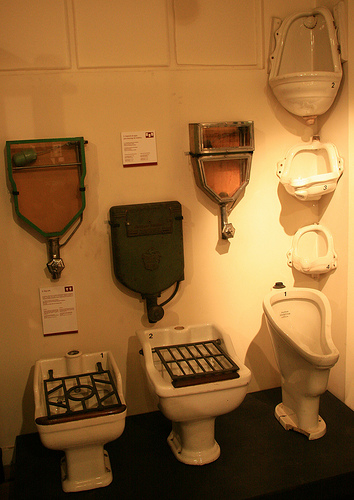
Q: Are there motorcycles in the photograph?
A: No, there are no motorcycles.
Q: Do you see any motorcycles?
A: No, there are no motorcycles.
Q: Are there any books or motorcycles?
A: No, there are no motorcycles or books.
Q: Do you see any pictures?
A: No, there are no pictures.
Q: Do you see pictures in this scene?
A: No, there are no pictures.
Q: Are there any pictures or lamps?
A: No, there are no pictures or lamps.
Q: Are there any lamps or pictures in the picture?
A: No, there are no pictures or lamps.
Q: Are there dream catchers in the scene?
A: No, there are no dream catchers.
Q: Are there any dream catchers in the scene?
A: No, there are no dream catchers.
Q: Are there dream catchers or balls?
A: No, there are no dream catchers or balls.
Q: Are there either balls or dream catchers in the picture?
A: No, there are no dream catchers or balls.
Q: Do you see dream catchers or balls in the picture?
A: No, there are no dream catchers or balls.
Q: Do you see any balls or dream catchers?
A: No, there are no dream catchers or balls.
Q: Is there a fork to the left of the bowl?
A: No, there is a toilet to the left of the bowl.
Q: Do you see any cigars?
A: No, there are no cigars.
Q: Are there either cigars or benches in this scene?
A: No, there are no cigars or benches.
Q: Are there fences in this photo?
A: No, there are no fences.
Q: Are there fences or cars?
A: No, there are no fences or cars.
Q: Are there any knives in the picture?
A: No, there are no knives.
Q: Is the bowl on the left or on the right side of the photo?
A: The bowl is on the right of the image.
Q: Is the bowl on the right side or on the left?
A: The bowl is on the right of the image.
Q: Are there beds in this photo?
A: No, there are no beds.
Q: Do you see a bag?
A: No, there are no bags.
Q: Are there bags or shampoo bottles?
A: No, there are no bags or shampoo bottles.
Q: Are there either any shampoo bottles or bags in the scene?
A: No, there are no bags or shampoo bottles.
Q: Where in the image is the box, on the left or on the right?
A: The box is on the right of the image.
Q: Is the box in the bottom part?
A: Yes, the box is in the bottom of the image.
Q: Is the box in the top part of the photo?
A: No, the box is in the bottom of the image.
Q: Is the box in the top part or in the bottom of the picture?
A: The box is in the bottom of the image.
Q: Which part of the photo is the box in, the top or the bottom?
A: The box is in the bottom of the image.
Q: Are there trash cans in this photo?
A: No, there are no trash cans.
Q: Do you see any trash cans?
A: No, there are no trash cans.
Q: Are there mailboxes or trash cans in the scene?
A: No, there are no trash cans or mailboxes.